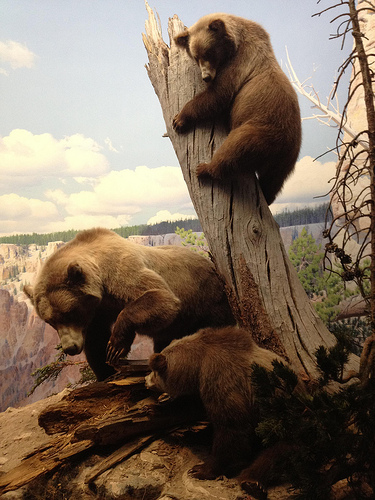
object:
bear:
[19, 224, 243, 386]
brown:
[201, 348, 235, 382]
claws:
[105, 342, 126, 363]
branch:
[328, 21, 357, 80]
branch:
[310, 128, 368, 202]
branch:
[319, 198, 367, 244]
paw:
[172, 106, 191, 137]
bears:
[143, 323, 326, 481]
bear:
[170, 12, 302, 206]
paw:
[193, 159, 224, 182]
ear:
[206, 18, 226, 35]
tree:
[141, 0, 360, 415]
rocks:
[0, 290, 20, 315]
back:
[80, 226, 215, 298]